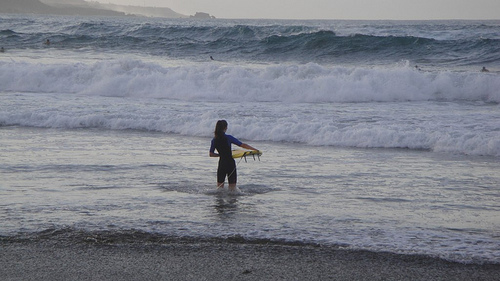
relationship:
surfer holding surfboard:
[208, 119, 258, 196] [230, 145, 260, 158]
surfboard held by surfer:
[230, 138, 264, 173] [206, 118, 264, 198]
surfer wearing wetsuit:
[209, 120, 260, 190] [212, 135, 246, 177]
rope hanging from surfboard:
[232, 146, 258, 166] [200, 140, 266, 158]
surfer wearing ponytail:
[209, 120, 260, 190] [214, 116, 223, 143]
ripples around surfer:
[180, 180, 242, 210] [209, 120, 260, 190]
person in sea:
[469, 56, 490, 80] [285, 56, 385, 164]